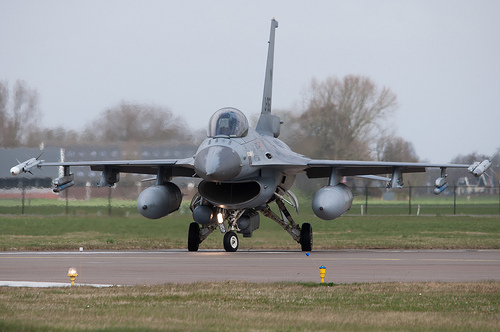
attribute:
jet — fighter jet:
[9, 18, 491, 253]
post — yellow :
[318, 265, 326, 282]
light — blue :
[65, 265, 77, 274]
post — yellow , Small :
[67, 268, 78, 282]